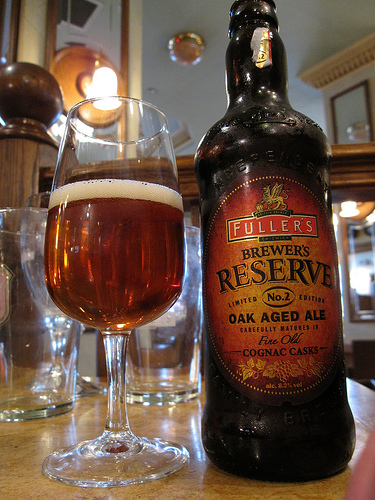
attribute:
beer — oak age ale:
[38, 177, 193, 340]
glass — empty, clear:
[1, 198, 81, 425]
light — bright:
[81, 60, 131, 112]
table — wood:
[5, 395, 367, 499]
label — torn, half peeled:
[247, 21, 277, 71]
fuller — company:
[223, 212, 320, 240]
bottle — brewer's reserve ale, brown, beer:
[192, 2, 354, 484]